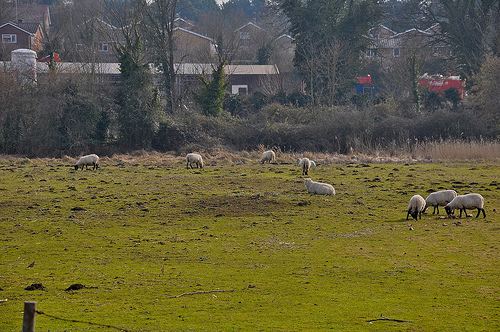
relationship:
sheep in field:
[406, 194, 426, 221] [0, 154, 498, 329]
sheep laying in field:
[297, 177, 340, 209] [183, 205, 293, 306]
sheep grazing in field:
[259, 147, 276, 163] [1, 139, 483, 330]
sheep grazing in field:
[442, 188, 485, 222] [1, 139, 483, 330]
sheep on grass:
[406, 194, 426, 221] [10, 142, 480, 317]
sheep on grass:
[421, 189, 457, 215] [10, 142, 480, 317]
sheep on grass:
[303, 177, 336, 196] [10, 142, 480, 317]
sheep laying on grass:
[303, 177, 336, 196] [10, 142, 480, 317]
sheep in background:
[73, 153, 100, 171] [5, 3, 485, 174]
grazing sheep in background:
[185, 152, 204, 170] [5, 3, 485, 174]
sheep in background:
[260, 150, 275, 164] [5, 3, 485, 174]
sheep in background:
[299, 157, 312, 176] [5, 3, 485, 174]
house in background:
[223, 18, 274, 68] [2, 2, 481, 143]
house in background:
[145, 26, 216, 63] [2, 2, 481, 143]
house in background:
[55, 16, 125, 67] [2, 2, 481, 143]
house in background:
[0, 12, 47, 63] [2, 2, 481, 143]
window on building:
[3, 32, 20, 43] [0, 8, 51, 64]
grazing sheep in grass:
[185, 152, 204, 170] [10, 142, 480, 317]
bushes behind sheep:
[1, 81, 498, 154] [442, 193, 486, 219]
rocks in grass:
[22, 281, 93, 293] [23, 207, 493, 327]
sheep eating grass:
[73, 153, 100, 171] [0, 157, 498, 330]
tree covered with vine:
[106, 31, 161, 155] [117, 55, 161, 150]